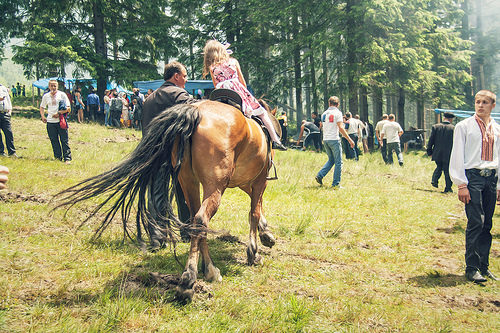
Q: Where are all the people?
A: In a field.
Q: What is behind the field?
A: A forest.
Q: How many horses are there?
A: One.